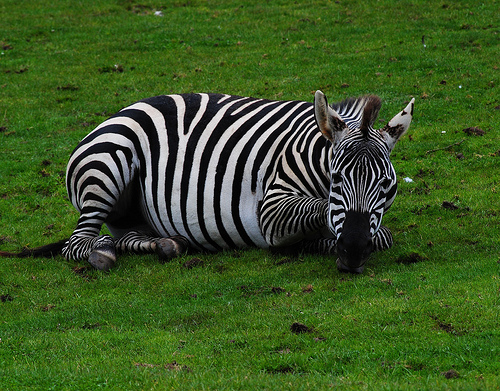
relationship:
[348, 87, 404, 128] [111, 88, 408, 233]
mane on zebra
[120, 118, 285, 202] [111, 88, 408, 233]
stripes on zebra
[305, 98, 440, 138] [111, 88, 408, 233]
ears on zebra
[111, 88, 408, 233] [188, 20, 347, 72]
zebra in grass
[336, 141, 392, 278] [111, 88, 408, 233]
face of zebra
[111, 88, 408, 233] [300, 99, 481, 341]
zebra has head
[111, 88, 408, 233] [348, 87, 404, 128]
zebra has mane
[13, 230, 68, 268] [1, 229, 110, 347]
hair on tail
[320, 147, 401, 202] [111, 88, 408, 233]
eyes of zebra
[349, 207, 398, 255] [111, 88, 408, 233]
nose of zebra